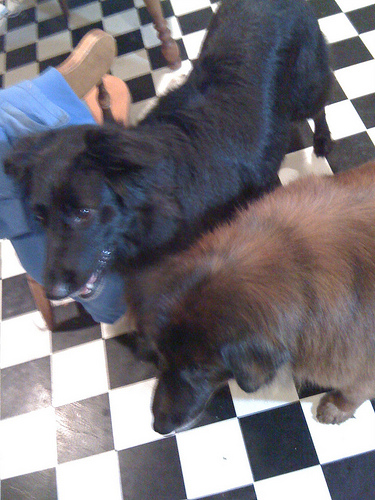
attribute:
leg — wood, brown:
[138, 1, 193, 77]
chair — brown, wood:
[3, 25, 137, 335]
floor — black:
[6, 4, 369, 499]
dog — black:
[11, 5, 315, 342]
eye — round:
[68, 203, 92, 223]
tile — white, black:
[45, 393, 120, 462]